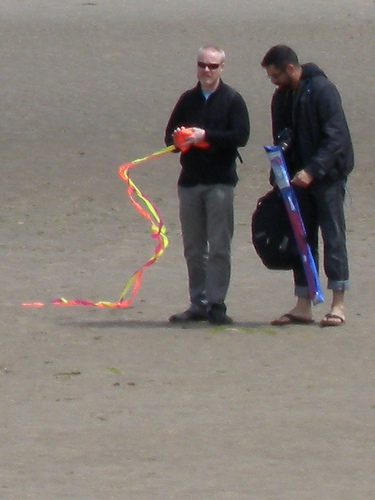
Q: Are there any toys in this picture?
A: Yes, there is a toy.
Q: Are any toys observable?
A: Yes, there is a toy.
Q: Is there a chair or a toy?
A: Yes, there is a toy.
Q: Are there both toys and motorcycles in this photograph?
A: No, there is a toy but no motorcycles.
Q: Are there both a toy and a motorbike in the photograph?
A: No, there is a toy but no motorcycles.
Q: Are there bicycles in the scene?
A: No, there are no bicycles.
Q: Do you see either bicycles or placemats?
A: No, there are no bicycles or placemats.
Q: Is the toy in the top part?
A: Yes, the toy is in the top of the image.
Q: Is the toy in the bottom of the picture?
A: No, the toy is in the top of the image.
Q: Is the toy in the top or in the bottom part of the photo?
A: The toy is in the top of the image.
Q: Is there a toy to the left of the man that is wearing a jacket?
A: Yes, there is a toy to the left of the man.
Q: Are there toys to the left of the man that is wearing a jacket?
A: Yes, there is a toy to the left of the man.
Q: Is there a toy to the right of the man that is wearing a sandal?
A: No, the toy is to the left of the man.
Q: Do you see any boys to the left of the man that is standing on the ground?
A: No, there is a toy to the left of the man.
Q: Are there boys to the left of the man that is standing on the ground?
A: No, there is a toy to the left of the man.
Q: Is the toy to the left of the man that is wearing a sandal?
A: Yes, the toy is to the left of the man.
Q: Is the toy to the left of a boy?
A: No, the toy is to the left of the man.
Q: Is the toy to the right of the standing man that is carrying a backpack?
A: No, the toy is to the left of the man.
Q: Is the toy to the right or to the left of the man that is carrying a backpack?
A: The toy is to the left of the man.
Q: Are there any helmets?
A: No, there are no helmets.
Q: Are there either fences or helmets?
A: No, there are no helmets or fences.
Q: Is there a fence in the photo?
A: No, there are no fences.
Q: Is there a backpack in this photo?
A: Yes, there is a backpack.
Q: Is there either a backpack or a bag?
A: Yes, there is a backpack.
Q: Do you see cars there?
A: No, there are no cars.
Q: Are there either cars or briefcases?
A: No, there are no cars or briefcases.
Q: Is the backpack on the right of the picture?
A: Yes, the backpack is on the right of the image.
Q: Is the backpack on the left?
A: No, the backpack is on the right of the image.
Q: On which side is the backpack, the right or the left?
A: The backpack is on the right of the image.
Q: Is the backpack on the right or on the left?
A: The backpack is on the right of the image.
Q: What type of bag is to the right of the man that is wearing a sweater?
A: The bag is a backpack.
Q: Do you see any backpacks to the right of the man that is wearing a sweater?
A: Yes, there is a backpack to the right of the man.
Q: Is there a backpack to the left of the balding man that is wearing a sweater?
A: No, the backpack is to the right of the man.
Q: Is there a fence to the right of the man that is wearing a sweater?
A: No, there is a backpack to the right of the man.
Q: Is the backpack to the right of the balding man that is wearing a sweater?
A: Yes, the backpack is to the right of the man.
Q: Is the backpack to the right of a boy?
A: No, the backpack is to the right of the man.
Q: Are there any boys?
A: No, there are no boys.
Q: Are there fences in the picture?
A: No, there are no fences.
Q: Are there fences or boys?
A: No, there are no fences or boys.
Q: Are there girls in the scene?
A: No, there are no girls.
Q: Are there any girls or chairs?
A: No, there are no girls or chairs.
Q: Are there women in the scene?
A: No, there are no women.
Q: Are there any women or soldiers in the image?
A: No, there are no women or soldiers.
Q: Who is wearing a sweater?
A: The man is wearing a sweater.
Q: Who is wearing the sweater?
A: The man is wearing a sweater.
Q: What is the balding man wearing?
A: The man is wearing a sweater.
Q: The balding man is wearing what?
A: The man is wearing a sweater.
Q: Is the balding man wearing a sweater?
A: Yes, the man is wearing a sweater.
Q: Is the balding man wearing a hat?
A: No, the man is wearing a sweater.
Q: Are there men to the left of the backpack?
A: Yes, there is a man to the left of the backpack.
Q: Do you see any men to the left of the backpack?
A: Yes, there is a man to the left of the backpack.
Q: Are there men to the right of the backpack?
A: No, the man is to the left of the backpack.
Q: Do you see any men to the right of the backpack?
A: No, the man is to the left of the backpack.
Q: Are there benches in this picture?
A: No, there are no benches.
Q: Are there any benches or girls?
A: No, there are no benches or girls.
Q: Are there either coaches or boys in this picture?
A: No, there are no boys or coaches.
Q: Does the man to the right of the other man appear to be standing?
A: Yes, the man is standing.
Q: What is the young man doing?
A: The man is standing.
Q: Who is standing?
A: The man is standing.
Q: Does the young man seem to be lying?
A: No, the man is standing.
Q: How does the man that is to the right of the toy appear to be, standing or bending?
A: The man is standing.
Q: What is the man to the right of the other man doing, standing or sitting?
A: The man is standing.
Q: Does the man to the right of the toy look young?
A: Yes, the man is young.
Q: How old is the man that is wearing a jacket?
A: The man is young.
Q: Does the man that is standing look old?
A: No, the man is young.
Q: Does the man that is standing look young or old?
A: The man is young.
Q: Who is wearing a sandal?
A: The man is wearing a sandal.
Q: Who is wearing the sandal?
A: The man is wearing a sandal.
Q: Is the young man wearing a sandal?
A: Yes, the man is wearing a sandal.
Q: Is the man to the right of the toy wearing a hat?
A: No, the man is wearing a sandal.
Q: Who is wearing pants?
A: The man is wearing pants.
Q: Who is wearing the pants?
A: The man is wearing pants.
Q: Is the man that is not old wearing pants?
A: Yes, the man is wearing pants.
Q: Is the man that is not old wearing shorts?
A: No, the man is wearing pants.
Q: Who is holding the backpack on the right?
A: The man is holding the backpack.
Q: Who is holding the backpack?
A: The man is holding the backpack.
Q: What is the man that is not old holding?
A: The man is holding the backpack.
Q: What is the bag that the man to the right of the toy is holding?
A: The bag is a backpack.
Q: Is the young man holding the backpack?
A: Yes, the man is holding the backpack.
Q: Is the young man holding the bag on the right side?
A: Yes, the man is holding the backpack.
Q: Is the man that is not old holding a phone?
A: No, the man is holding the backpack.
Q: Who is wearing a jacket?
A: The man is wearing a jacket.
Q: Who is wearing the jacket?
A: The man is wearing a jacket.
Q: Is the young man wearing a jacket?
A: Yes, the man is wearing a jacket.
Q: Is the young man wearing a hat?
A: No, the man is wearing a jacket.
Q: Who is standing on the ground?
A: The man is standing on the ground.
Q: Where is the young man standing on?
A: The man is standing on the ground.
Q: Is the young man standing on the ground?
A: Yes, the man is standing on the ground.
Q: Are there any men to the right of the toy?
A: Yes, there is a man to the right of the toy.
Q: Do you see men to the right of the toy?
A: Yes, there is a man to the right of the toy.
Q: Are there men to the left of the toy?
A: No, the man is to the right of the toy.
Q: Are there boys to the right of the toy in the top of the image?
A: No, there is a man to the right of the toy.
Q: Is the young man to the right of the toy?
A: Yes, the man is to the right of the toy.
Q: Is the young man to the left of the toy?
A: No, the man is to the right of the toy.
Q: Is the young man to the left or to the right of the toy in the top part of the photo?
A: The man is to the right of the toy.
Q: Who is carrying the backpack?
A: The man is carrying the backpack.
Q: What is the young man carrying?
A: The man is carrying a backpack.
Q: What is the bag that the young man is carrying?
A: The bag is a backpack.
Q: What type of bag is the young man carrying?
A: The man is carrying a backpack.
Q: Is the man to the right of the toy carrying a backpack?
A: Yes, the man is carrying a backpack.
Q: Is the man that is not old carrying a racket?
A: No, the man is carrying a backpack.